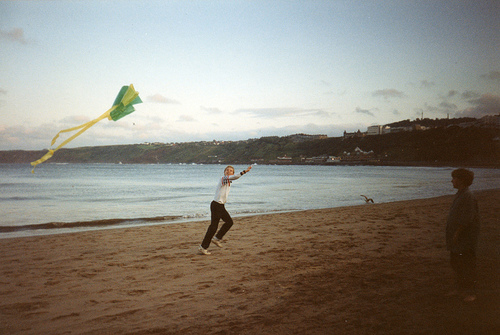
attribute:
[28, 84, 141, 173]
kite — green, yellow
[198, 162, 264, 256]
man — standing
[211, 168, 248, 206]
shirt — white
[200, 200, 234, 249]
pants — black, dark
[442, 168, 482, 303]
boy — standing, barefoot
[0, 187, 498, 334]
sand — brown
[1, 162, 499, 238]
water — blue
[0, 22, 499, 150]
clouds — white, gray